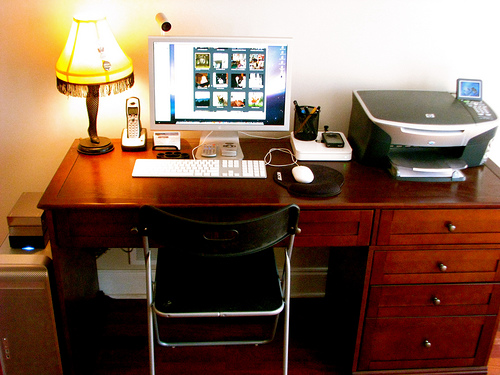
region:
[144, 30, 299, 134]
the computer monitor on the desk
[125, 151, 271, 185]
the keyboard on the desk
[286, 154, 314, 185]
the mouse on the desk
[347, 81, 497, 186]
the printer on the desk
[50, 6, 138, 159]
the lamp on the desk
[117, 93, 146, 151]
the cordless phone on the desk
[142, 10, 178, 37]
the camera on the monitor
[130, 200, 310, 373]
the chair in front of the desk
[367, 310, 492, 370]
the bottom drawer of the desk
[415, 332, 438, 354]
the bottom knob on the bottom drawer of the desk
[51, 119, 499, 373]
a wooden desk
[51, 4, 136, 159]
a miniture leg lamp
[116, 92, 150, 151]
a black and silver landline phone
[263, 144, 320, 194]
a white computer mouse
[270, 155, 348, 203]
a blcak computer mouse pad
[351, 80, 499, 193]
a black and silver computer printer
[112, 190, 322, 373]
a black folding chair at a desk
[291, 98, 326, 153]
a black pen and pencil holder cup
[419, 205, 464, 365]
silver drawer pulls on the desk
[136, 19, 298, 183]
a desktop computer and keyboard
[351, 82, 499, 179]
printer sitting on desk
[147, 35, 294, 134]
computer screen standing on desk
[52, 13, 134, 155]
one legged lamp on desk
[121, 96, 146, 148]
telephone on charge stand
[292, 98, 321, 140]
pencil holder with pens and pencils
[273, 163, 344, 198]
mouse sitting on mousepad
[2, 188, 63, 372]
tower for desktop computer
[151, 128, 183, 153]
business cards in holder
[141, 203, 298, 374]
desk chair at desk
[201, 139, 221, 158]
remote control for television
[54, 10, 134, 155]
small desk lamp resembling ladies leg in a fishnet stocking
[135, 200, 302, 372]
chrome chair with black seat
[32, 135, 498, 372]
dark stained wooden desk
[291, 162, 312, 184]
white computer mouse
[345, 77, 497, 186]
black and silver printer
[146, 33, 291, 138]
desktop computer monitor turned on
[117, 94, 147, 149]
silver cordless phone on charger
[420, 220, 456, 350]
brushed nickel drawer pulls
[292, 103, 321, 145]
black mesh pencil cup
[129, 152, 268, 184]
white computer keyboard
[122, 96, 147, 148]
Wireless phones sitting on a desk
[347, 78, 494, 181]
Printer for a computer sitting on a desk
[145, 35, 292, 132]
Flatscreen monitor for computer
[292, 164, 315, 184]
Computer mouse sitting on a mousepad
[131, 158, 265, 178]
Keyboard for a computer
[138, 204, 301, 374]
Foldable chair sitting at a desk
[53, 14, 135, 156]
Table lamp sitting on a desk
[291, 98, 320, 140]
Mesh metal cup full of writing utensils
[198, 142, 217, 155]
Remote-control for electronic device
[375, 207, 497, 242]
Top drawer on a desk